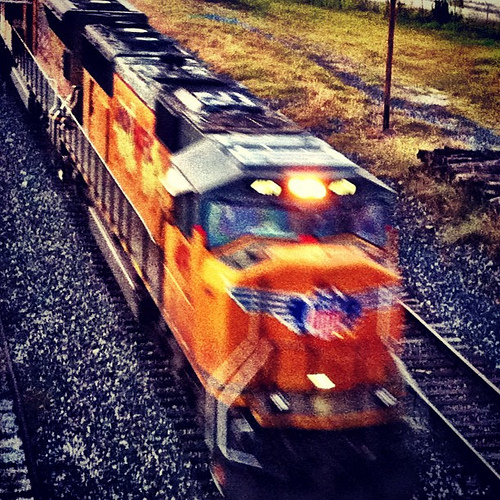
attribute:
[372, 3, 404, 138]
log — thin, wooden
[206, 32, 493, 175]
ground — black, silver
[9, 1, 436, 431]
train — speeding, orange, large, in motion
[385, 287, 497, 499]
train tracks — unused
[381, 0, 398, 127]
pole — utility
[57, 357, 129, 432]
rocks — silver, black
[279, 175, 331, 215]
light — bright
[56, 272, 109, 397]
rocks — black, silver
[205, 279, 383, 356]
logo — blurry, white and blue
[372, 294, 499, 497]
track — train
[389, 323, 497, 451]
track — train, metal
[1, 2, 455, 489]
train — traveling, large, orange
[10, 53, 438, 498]
train — bright orange, in motion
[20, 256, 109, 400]
rocks — black, silver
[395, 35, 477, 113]
grass — green color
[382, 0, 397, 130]
post — metal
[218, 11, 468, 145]
trail — bare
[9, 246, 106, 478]
rocks — silver, black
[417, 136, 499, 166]
logs — wood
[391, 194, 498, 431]
rocks — black, silver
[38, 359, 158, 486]
rocks — silver, black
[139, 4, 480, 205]
area — green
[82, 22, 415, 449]
train car — orange